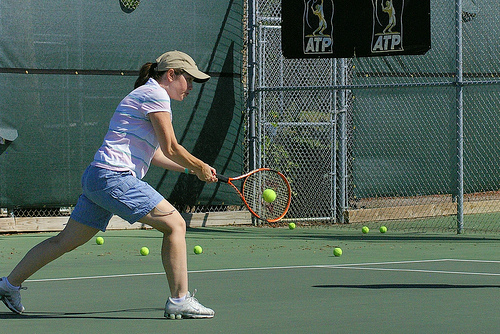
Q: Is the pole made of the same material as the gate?
A: Yes, both the pole and the gate are made of metal.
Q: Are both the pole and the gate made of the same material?
A: Yes, both the pole and the gate are made of metal.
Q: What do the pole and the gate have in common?
A: The material, both the pole and the gate are metallic.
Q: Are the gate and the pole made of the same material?
A: Yes, both the gate and the pole are made of metal.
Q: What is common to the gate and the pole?
A: The material, both the gate and the pole are metallic.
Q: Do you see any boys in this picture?
A: No, there are no boys.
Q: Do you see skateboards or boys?
A: No, there are no boys or skateboards.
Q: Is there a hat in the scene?
A: Yes, there is a hat.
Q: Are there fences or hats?
A: Yes, there is a hat.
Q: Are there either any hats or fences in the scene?
A: Yes, there is a hat.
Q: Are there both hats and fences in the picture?
A: Yes, there are both a hat and a fence.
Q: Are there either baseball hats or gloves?
A: Yes, there is a baseball hat.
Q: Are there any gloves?
A: No, there are no gloves.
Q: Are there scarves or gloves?
A: No, there are no gloves or scarves.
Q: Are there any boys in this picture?
A: No, there are no boys.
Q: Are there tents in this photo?
A: No, there are no tents.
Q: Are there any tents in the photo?
A: No, there are no tents.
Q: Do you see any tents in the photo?
A: No, there are no tents.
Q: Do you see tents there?
A: No, there are no tents.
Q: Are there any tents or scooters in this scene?
A: No, there are no tents or scooters.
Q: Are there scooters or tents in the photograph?
A: No, there are no tents or scooters.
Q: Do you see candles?
A: No, there are no candles.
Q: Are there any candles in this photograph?
A: No, there are no candles.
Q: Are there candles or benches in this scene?
A: No, there are no candles or benches.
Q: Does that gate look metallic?
A: Yes, the gate is metallic.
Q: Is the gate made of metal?
A: Yes, the gate is made of metal.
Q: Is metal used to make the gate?
A: Yes, the gate is made of metal.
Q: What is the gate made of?
A: The gate is made of metal.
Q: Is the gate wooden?
A: No, the gate is metallic.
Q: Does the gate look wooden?
A: No, the gate is metallic.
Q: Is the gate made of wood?
A: No, the gate is made of metal.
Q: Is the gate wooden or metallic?
A: The gate is metallic.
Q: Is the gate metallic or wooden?
A: The gate is metallic.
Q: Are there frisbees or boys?
A: No, there are no boys or frisbees.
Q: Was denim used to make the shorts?
A: Yes, the shorts are made of denim.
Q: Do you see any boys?
A: No, there are no boys.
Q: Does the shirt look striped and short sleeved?
A: Yes, the shirt is striped and short sleeved.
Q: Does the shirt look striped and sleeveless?
A: No, the shirt is striped but short sleeved.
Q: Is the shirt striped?
A: Yes, the shirt is striped.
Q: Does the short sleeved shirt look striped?
A: Yes, the shirt is striped.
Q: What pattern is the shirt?
A: The shirt is striped.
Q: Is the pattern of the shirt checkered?
A: No, the shirt is striped.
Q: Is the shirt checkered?
A: No, the shirt is striped.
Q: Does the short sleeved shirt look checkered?
A: No, the shirt is striped.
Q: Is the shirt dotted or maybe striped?
A: The shirt is striped.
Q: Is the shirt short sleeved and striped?
A: Yes, the shirt is short sleeved and striped.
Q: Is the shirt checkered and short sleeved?
A: No, the shirt is short sleeved but striped.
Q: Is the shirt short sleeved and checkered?
A: No, the shirt is short sleeved but striped.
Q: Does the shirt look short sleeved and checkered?
A: No, the shirt is short sleeved but striped.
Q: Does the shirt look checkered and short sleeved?
A: No, the shirt is short sleeved but striped.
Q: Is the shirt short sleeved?
A: Yes, the shirt is short sleeved.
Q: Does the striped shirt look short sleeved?
A: Yes, the shirt is short sleeved.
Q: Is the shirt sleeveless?
A: No, the shirt is short sleeved.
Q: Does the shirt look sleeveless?
A: No, the shirt is short sleeved.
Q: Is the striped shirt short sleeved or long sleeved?
A: The shirt is short sleeved.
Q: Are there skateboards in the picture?
A: No, there are no skateboards.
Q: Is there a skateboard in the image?
A: No, there are no skateboards.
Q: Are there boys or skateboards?
A: No, there are no skateboards or boys.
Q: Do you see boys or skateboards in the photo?
A: No, there are no skateboards or boys.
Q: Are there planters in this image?
A: No, there are no planters.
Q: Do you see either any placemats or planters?
A: No, there are no planters or placemats.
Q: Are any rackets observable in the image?
A: Yes, there is a racket.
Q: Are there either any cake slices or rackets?
A: Yes, there is a racket.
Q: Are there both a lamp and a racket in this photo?
A: No, there is a racket but no lamps.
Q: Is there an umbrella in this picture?
A: No, there are no umbrellas.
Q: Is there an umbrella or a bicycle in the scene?
A: No, there are no umbrellas or bicycles.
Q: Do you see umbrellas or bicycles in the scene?
A: No, there are no umbrellas or bicycles.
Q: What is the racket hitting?
A: The racket is hitting the tennis ball.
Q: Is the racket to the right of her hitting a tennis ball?
A: Yes, the tennis racket is hitting a tennis ball.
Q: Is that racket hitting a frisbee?
A: No, the racket is hitting a tennis ball.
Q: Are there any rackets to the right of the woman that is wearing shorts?
A: Yes, there is a racket to the right of the woman.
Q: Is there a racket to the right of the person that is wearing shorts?
A: Yes, there is a racket to the right of the woman.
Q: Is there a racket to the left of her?
A: No, the racket is to the right of the woman.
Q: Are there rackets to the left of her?
A: No, the racket is to the right of the woman.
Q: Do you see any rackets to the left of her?
A: No, the racket is to the right of the woman.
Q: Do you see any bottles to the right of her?
A: No, there is a racket to the right of the woman.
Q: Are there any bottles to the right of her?
A: No, there is a racket to the right of the woman.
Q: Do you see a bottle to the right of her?
A: No, there is a racket to the right of the woman.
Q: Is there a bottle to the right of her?
A: No, there is a racket to the right of the woman.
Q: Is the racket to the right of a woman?
A: Yes, the racket is to the right of a woman.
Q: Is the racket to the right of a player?
A: No, the racket is to the right of a woman.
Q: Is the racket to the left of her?
A: No, the racket is to the right of the woman.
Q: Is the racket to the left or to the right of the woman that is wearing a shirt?
A: The racket is to the right of the woman.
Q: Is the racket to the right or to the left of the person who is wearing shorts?
A: The racket is to the right of the woman.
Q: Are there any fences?
A: Yes, there is a fence.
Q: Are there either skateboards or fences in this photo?
A: Yes, there is a fence.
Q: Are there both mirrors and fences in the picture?
A: No, there is a fence but no mirrors.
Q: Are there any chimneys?
A: No, there are no chimneys.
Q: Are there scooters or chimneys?
A: No, there are no chimneys or scooters.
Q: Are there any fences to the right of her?
A: Yes, there is a fence to the right of the woman.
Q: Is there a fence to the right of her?
A: Yes, there is a fence to the right of the woman.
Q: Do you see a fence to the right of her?
A: Yes, there is a fence to the right of the woman.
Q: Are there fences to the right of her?
A: Yes, there is a fence to the right of the woman.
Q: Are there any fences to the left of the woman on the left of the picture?
A: No, the fence is to the right of the woman.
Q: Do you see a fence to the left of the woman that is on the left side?
A: No, the fence is to the right of the woman.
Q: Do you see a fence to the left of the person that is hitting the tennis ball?
A: No, the fence is to the right of the woman.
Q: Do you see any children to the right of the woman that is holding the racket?
A: No, there is a fence to the right of the woman.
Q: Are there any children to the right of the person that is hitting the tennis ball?
A: No, there is a fence to the right of the woman.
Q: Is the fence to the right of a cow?
A: No, the fence is to the right of a woman.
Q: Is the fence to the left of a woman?
A: No, the fence is to the right of a woman.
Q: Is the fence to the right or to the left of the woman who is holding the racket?
A: The fence is to the right of the woman.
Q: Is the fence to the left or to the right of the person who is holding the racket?
A: The fence is to the right of the woman.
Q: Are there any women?
A: Yes, there is a woman.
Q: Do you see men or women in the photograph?
A: Yes, there is a woman.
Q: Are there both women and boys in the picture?
A: No, there is a woman but no boys.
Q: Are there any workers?
A: No, there are no workers.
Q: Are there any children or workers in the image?
A: No, there are no workers or children.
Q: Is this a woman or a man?
A: This is a woman.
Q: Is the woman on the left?
A: Yes, the woman is on the left of the image.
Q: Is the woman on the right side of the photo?
A: No, the woman is on the left of the image.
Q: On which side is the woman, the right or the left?
A: The woman is on the left of the image.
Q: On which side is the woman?
A: The woman is on the left of the image.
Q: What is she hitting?
A: The woman is hitting the tennis ball.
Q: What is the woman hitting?
A: The woman is hitting the tennis ball.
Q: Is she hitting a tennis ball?
A: Yes, the woman is hitting a tennis ball.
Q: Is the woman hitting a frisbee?
A: No, the woman is hitting a tennis ball.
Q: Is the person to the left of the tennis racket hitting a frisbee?
A: No, the woman is hitting a tennis ball.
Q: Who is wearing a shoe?
A: The woman is wearing a shoe.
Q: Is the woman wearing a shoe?
A: Yes, the woman is wearing a shoe.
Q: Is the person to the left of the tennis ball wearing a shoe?
A: Yes, the woman is wearing a shoe.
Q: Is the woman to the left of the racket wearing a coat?
A: No, the woman is wearing a shoe.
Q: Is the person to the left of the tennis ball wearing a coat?
A: No, the woman is wearing a shoe.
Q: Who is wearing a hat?
A: The woman is wearing a hat.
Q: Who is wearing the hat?
A: The woman is wearing a hat.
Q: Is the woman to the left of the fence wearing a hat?
A: Yes, the woman is wearing a hat.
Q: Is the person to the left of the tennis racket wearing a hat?
A: Yes, the woman is wearing a hat.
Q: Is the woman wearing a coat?
A: No, the woman is wearing a hat.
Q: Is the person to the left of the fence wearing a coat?
A: No, the woman is wearing a hat.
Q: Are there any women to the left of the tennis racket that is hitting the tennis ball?
A: Yes, there is a woman to the left of the tennis racket.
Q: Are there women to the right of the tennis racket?
A: No, the woman is to the left of the tennis racket.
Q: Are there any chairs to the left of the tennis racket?
A: No, there is a woman to the left of the tennis racket.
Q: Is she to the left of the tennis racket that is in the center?
A: Yes, the woman is to the left of the racket.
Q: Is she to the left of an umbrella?
A: No, the woman is to the left of the racket.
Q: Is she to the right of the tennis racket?
A: No, the woman is to the left of the tennis racket.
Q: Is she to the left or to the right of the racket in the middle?
A: The woman is to the left of the tennis racket.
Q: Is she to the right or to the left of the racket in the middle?
A: The woman is to the left of the tennis racket.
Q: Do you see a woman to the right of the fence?
A: No, the woman is to the left of the fence.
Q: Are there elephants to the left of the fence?
A: No, there is a woman to the left of the fence.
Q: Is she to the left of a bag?
A: No, the woman is to the left of the fence.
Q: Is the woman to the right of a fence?
A: No, the woman is to the left of a fence.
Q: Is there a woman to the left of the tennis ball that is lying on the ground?
A: Yes, there is a woman to the left of the tennis ball.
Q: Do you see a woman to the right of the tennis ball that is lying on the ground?
A: No, the woman is to the left of the tennis ball.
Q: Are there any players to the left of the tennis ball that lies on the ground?
A: No, there is a woman to the left of the tennis ball.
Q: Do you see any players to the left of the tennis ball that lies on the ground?
A: No, there is a woman to the left of the tennis ball.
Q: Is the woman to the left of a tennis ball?
A: Yes, the woman is to the left of a tennis ball.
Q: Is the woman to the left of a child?
A: No, the woman is to the left of a tennis ball.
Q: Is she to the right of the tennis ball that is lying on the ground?
A: No, the woman is to the left of the tennis ball.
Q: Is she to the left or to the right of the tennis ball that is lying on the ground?
A: The woman is to the left of the tennis ball.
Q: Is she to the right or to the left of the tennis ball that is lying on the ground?
A: The woman is to the left of the tennis ball.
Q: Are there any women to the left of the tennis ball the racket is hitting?
A: Yes, there is a woman to the left of the tennis ball.